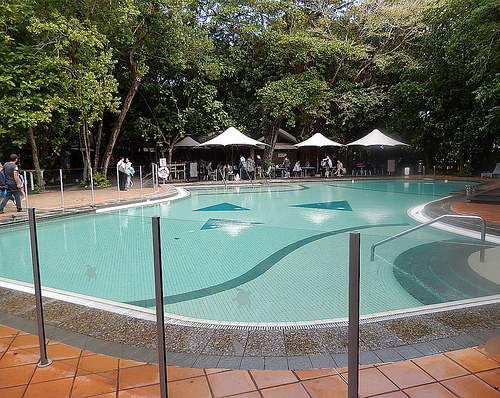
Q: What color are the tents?
A: White.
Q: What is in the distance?
A: Trees.